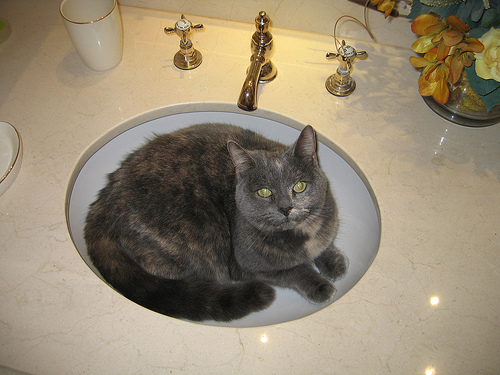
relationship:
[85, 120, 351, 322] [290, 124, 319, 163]
cat has ear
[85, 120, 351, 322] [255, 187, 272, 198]
cat has an eye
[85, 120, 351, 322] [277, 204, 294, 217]
cat has a nose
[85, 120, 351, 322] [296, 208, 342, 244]
cat has whiskers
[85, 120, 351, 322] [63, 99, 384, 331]
cat in sink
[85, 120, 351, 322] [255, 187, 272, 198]
cat has eye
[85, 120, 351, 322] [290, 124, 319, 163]
cat has an ear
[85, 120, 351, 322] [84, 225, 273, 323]
cat has a tail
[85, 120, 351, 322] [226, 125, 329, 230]
cat has head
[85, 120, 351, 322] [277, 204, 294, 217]
cat has nose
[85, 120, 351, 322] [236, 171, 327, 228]
cat has face